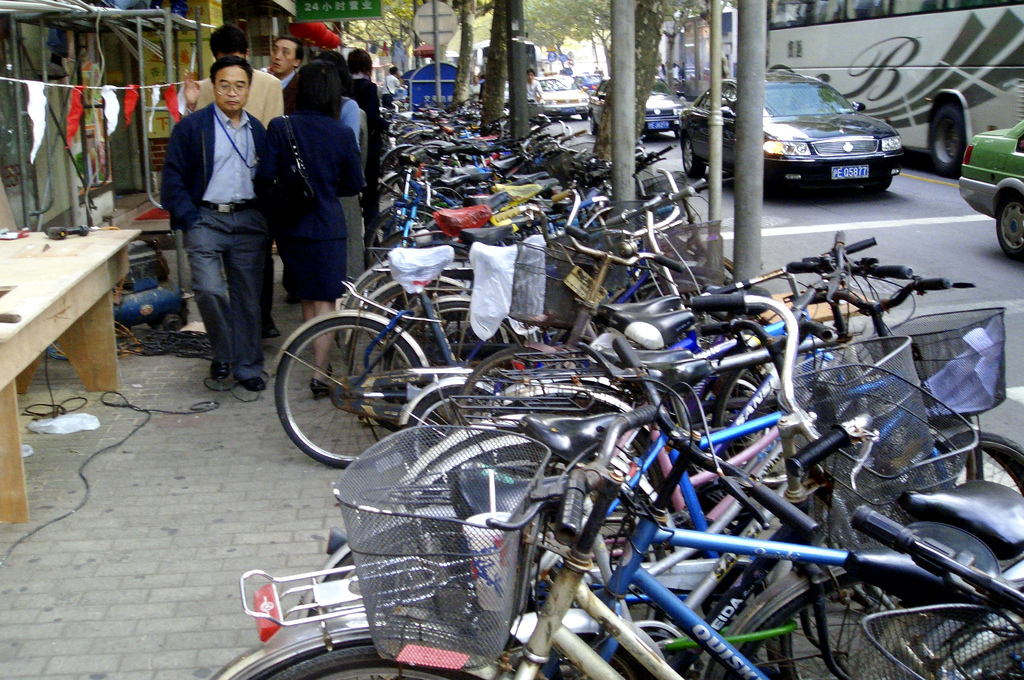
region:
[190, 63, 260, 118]
the head of a man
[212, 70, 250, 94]
the eyes of a man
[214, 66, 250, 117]
the face of a man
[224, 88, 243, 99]
the nose of a man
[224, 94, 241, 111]
the mouth of a man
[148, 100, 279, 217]
the shirt of a man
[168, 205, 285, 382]
the pants of a man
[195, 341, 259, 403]
the shoes of a man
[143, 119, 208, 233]
the right arm of a man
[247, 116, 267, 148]
the shoulder of a man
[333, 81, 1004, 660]
large line of bicycles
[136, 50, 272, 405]
man in blue jacket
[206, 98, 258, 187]
blue lanyard on man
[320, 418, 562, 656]
silver basket on bicycle in front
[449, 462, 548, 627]
disposable KFC cup in basket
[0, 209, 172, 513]
light colored wooden table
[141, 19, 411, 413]
group of people on sidewalk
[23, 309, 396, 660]
grey brick sidewalk by bicycles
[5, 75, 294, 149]
white and red banner flags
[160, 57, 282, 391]
the man wearing a blue jacket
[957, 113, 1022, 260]
the partly visible green car on the road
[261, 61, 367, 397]
the woman in blue walking on the sidewalk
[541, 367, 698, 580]
a bike on the sidewalk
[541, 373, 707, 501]
a bike on the sidewalk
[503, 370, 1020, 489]
a bike on the sidewalk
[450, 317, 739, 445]
a bike on the sidewalk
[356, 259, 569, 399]
a bike on the sidewalk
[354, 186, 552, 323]
a bike on the sidewalk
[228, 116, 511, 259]
a bike on the sidewalk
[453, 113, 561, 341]
a bike on the sidewalk